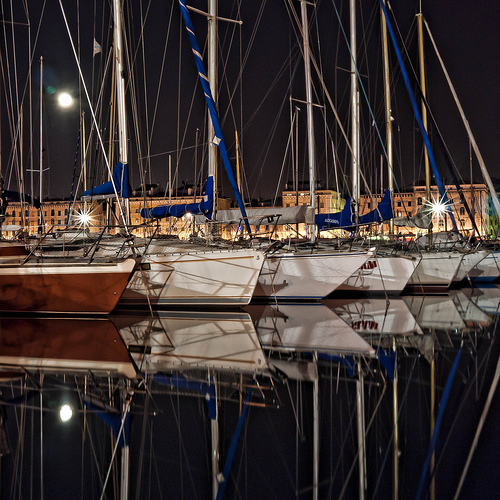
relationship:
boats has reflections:
[14, 195, 484, 324] [27, 320, 499, 422]